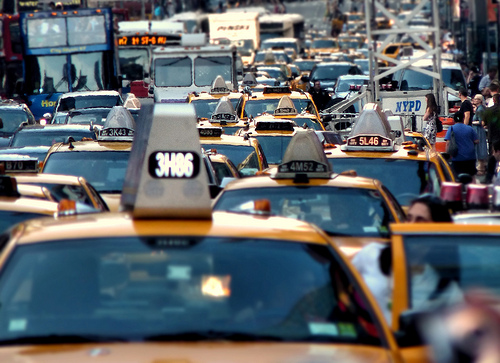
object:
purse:
[446, 125, 459, 158]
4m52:
[291, 161, 314, 170]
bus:
[113, 20, 187, 95]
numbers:
[118, 36, 167, 45]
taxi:
[234, 108, 325, 138]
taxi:
[209, 160, 406, 258]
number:
[102, 129, 134, 136]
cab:
[0, 102, 500, 363]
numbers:
[155, 152, 195, 178]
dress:
[471, 105, 488, 159]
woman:
[471, 93, 488, 176]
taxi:
[35, 128, 134, 213]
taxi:
[322, 133, 455, 211]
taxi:
[235, 86, 320, 119]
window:
[0, 234, 386, 345]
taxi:
[0, 154, 110, 217]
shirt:
[307, 86, 332, 112]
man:
[453, 88, 475, 127]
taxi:
[234, 86, 326, 132]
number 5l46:
[359, 137, 378, 145]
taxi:
[197, 128, 269, 172]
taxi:
[0, 174, 103, 270]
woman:
[443, 111, 480, 184]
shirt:
[444, 122, 480, 162]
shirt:
[350, 242, 465, 338]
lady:
[347, 192, 467, 327]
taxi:
[199, 147, 239, 199]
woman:
[423, 93, 443, 151]